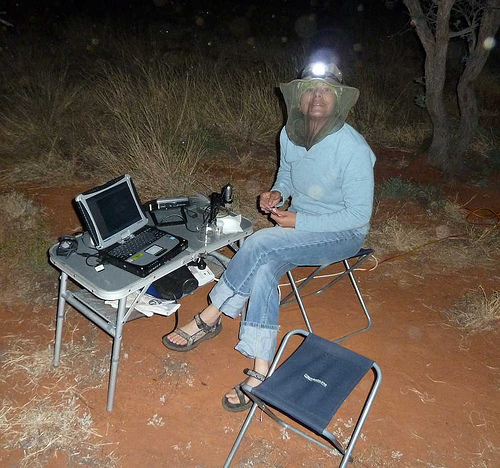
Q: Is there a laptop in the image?
A: Yes, there is a laptop.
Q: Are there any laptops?
A: Yes, there is a laptop.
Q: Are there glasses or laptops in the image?
A: Yes, there is a laptop.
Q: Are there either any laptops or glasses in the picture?
A: Yes, there is a laptop.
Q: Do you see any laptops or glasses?
A: Yes, there is a laptop.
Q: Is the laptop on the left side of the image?
A: Yes, the laptop is on the left of the image.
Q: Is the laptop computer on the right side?
A: No, the laptop computer is on the left of the image.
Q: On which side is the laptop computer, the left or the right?
A: The laptop computer is on the left of the image.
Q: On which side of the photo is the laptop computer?
A: The laptop computer is on the left of the image.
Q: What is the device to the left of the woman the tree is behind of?
A: The device is a laptop.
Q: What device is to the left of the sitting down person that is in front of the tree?
A: The device is a laptop.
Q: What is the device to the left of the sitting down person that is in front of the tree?
A: The device is a laptop.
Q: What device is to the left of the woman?
A: The device is a laptop.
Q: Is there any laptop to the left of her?
A: Yes, there is a laptop to the left of the woman.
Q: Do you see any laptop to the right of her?
A: No, the laptop is to the left of the woman.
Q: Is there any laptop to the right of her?
A: No, the laptop is to the left of the woman.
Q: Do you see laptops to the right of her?
A: No, the laptop is to the left of the woman.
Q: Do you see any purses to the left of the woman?
A: No, there is a laptop to the left of the woman.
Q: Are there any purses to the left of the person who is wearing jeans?
A: No, there is a laptop to the left of the woman.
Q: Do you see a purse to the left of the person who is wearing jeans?
A: No, there is a laptop to the left of the woman.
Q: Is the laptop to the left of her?
A: Yes, the laptop is to the left of the woman.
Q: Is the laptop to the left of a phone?
A: No, the laptop is to the left of the woman.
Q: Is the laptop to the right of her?
A: No, the laptop is to the left of the woman.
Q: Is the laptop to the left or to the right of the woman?
A: The laptop is to the left of the woman.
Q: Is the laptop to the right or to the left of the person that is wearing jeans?
A: The laptop is to the left of the woman.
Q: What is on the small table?
A: The laptop is on the table.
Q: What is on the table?
A: The laptop is on the table.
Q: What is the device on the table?
A: The device is a laptop.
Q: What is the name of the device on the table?
A: The device is a laptop.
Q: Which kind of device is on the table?
A: The device is a laptop.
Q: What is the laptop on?
A: The laptop is on the table.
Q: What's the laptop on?
A: The laptop is on the table.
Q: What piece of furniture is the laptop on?
A: The laptop is on the table.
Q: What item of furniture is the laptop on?
A: The laptop is on the table.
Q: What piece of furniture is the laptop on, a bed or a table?
A: The laptop is on a table.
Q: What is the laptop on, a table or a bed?
A: The laptop is on a table.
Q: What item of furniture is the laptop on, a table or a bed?
A: The laptop is on a table.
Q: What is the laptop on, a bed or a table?
A: The laptop is on a table.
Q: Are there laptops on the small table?
A: Yes, there is a laptop on the table.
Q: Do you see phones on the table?
A: No, there is a laptop on the table.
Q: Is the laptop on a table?
A: Yes, the laptop is on a table.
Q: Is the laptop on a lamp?
A: No, the laptop is on a table.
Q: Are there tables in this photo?
A: Yes, there is a table.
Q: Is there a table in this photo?
A: Yes, there is a table.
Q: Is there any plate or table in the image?
A: Yes, there is a table.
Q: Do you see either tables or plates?
A: Yes, there is a table.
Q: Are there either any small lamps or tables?
A: Yes, there is a small table.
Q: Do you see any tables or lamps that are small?
A: Yes, the table is small.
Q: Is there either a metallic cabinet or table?
A: Yes, there is a metal table.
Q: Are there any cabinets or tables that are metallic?
A: Yes, the table is metallic.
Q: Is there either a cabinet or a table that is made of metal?
A: Yes, the table is made of metal.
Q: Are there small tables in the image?
A: Yes, there is a small table.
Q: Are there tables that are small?
A: Yes, there is a table that is small.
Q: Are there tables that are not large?
A: Yes, there is a small table.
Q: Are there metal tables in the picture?
A: Yes, there is a metal table.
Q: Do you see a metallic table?
A: Yes, there is a metal table.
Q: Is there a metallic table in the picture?
A: Yes, there is a metal table.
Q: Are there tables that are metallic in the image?
A: Yes, there is a metal table.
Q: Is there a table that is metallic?
A: Yes, there is a table that is metallic.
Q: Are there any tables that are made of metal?
A: Yes, there is a table that is made of metal.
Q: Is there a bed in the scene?
A: No, there are no beds.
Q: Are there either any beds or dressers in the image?
A: No, there are no beds or dressers.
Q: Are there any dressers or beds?
A: No, there are no beds or dressers.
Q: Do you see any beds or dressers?
A: No, there are no beds or dressers.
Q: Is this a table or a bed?
A: This is a table.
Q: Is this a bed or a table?
A: This is a table.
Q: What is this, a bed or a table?
A: This is a table.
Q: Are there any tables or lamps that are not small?
A: No, there is a table but it is small.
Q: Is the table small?
A: Yes, the table is small.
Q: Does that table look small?
A: Yes, the table is small.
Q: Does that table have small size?
A: Yes, the table is small.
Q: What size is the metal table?
A: The table is small.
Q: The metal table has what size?
A: The table is small.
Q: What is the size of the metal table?
A: The table is small.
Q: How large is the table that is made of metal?
A: The table is small.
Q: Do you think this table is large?
A: No, the table is small.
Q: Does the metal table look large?
A: No, the table is small.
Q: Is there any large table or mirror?
A: No, there is a table but it is small.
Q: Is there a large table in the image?
A: No, there is a table but it is small.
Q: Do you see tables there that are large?
A: No, there is a table but it is small.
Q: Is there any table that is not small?
A: No, there is a table but it is small.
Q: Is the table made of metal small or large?
A: The table is small.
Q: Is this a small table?
A: Yes, this is a small table.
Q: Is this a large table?
A: No, this is a small table.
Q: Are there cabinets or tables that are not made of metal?
A: No, there is a table but it is made of metal.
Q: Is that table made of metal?
A: Yes, the table is made of metal.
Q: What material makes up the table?
A: The table is made of metal.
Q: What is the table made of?
A: The table is made of metal.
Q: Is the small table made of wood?
A: No, the table is made of metal.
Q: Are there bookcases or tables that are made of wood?
A: No, there is a table but it is made of metal.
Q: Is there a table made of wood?
A: No, there is a table but it is made of metal.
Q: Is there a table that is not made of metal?
A: No, there is a table but it is made of metal.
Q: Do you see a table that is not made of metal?
A: No, there is a table but it is made of metal.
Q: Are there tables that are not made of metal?
A: No, there is a table but it is made of metal.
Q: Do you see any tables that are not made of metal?
A: No, there is a table but it is made of metal.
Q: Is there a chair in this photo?
A: Yes, there is a chair.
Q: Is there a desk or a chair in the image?
A: Yes, there is a chair.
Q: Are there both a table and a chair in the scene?
A: Yes, there are both a chair and a table.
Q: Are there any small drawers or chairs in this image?
A: Yes, there is a small chair.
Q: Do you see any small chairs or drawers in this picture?
A: Yes, there is a small chair.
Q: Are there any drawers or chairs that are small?
A: Yes, the chair is small.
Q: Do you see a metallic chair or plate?
A: Yes, there is a metal chair.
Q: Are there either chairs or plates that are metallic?
A: Yes, the chair is metallic.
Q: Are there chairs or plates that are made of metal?
A: Yes, the chair is made of metal.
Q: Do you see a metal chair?
A: Yes, there is a chair that is made of metal.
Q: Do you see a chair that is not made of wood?
A: Yes, there is a chair that is made of metal.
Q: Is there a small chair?
A: Yes, there is a small chair.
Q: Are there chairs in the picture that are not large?
A: Yes, there is a small chair.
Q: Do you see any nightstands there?
A: No, there are no nightstands.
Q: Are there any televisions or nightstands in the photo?
A: No, there are no nightstands or televisions.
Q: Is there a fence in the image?
A: No, there are no fences.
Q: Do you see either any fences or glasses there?
A: No, there are no fences or glasses.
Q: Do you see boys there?
A: No, there are no boys.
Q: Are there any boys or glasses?
A: No, there are no boys or glasses.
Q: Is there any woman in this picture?
A: Yes, there is a woman.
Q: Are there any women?
A: Yes, there is a woman.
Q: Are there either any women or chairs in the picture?
A: Yes, there is a woman.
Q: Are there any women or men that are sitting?
A: Yes, the woman is sitting.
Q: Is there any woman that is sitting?
A: Yes, there is a woman that is sitting.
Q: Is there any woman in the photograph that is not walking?
A: Yes, there is a woman that is sitting.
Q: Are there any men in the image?
A: No, there are no men.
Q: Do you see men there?
A: No, there are no men.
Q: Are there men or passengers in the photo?
A: No, there are no men or passengers.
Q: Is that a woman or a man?
A: That is a woman.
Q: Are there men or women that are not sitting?
A: No, there is a woman but she is sitting.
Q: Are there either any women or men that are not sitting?
A: No, there is a woman but she is sitting.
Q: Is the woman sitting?
A: Yes, the woman is sitting.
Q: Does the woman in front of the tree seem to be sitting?
A: Yes, the woman is sitting.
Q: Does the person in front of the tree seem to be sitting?
A: Yes, the woman is sitting.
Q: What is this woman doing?
A: The woman is sitting.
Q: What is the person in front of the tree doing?
A: The woman is sitting.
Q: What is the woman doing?
A: The woman is sitting.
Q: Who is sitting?
A: The woman is sitting.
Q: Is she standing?
A: No, the woman is sitting.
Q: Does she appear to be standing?
A: No, the woman is sitting.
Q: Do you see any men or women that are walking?
A: No, there is a woman but she is sitting.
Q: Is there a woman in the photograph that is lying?
A: No, there is a woman but she is sitting.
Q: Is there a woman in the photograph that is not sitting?
A: No, there is a woman but she is sitting.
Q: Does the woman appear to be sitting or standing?
A: The woman is sitting.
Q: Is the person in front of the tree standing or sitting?
A: The woman is sitting.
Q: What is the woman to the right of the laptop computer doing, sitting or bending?
A: The woman is sitting.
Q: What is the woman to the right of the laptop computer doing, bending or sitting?
A: The woman is sitting.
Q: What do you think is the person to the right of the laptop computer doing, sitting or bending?
A: The woman is sitting.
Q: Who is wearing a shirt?
A: The woman is wearing a shirt.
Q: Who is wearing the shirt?
A: The woman is wearing a shirt.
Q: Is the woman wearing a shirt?
A: Yes, the woman is wearing a shirt.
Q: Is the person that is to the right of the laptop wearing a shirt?
A: Yes, the woman is wearing a shirt.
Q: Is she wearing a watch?
A: No, the woman is wearing a shirt.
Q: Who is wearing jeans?
A: The woman is wearing jeans.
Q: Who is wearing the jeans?
A: The woman is wearing jeans.